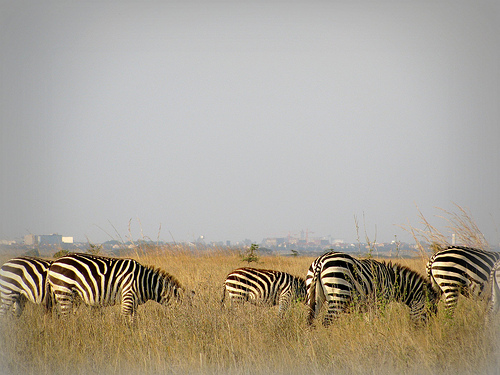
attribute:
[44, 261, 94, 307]
stripe — brown, white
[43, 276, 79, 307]
stripe — white, brown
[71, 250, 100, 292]
stripe — brown, white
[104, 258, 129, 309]
stripe — white, brown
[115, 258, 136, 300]
stripe — brown, white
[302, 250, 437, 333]
stripes — brown, white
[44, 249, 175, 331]
zebra — eating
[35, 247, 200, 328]
zebra — eating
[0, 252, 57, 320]
zebra — eating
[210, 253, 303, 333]
zebra — eating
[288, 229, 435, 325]
zebra — eating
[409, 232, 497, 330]
zebra — eating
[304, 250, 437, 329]
zebra's fur — striped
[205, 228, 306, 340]
stripes — white, brown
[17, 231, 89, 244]
building — white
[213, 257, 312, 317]
zebra — striped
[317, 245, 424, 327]
fur — striped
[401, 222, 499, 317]
zebra's fur — striped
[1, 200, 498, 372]
grass — tall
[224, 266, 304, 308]
stripes — white, brown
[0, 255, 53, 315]
zebra — eating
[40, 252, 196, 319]
zebra — eating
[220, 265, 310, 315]
zebra — eating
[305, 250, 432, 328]
zebra — eating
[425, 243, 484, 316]
zebra — eating